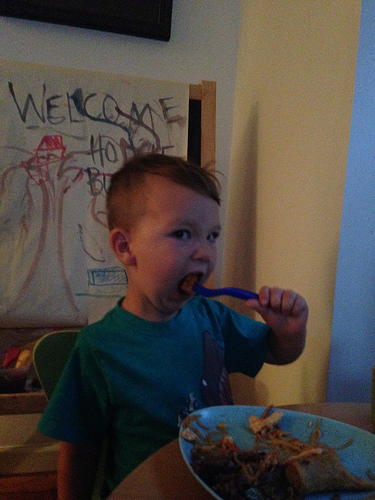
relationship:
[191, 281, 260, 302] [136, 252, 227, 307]
spoon in mouth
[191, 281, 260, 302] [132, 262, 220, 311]
spoon in mouth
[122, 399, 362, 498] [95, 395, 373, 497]
table made of wood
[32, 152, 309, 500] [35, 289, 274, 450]
baby wearing tshirt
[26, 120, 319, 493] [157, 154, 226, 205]
baby has hair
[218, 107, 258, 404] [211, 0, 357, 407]
shadow on wall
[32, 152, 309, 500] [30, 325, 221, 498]
baby in a chair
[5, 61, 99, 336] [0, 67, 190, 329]
art work on art work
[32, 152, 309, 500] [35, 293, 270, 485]
baby wearing shirt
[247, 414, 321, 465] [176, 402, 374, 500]
noodles on bowl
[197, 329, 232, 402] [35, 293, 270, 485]
shark on shirt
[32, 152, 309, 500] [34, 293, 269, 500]
baby wearing shirt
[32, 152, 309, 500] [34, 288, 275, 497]
baby wearing shirt